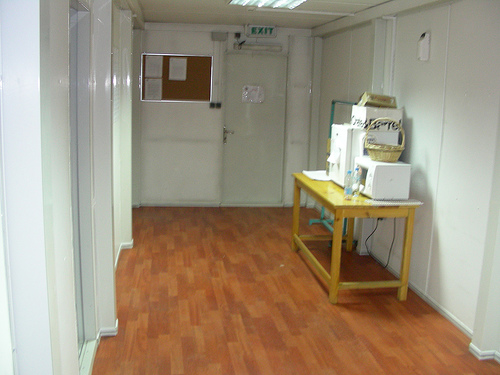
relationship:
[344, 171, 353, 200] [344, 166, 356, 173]
bottles with tops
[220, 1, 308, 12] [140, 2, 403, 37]
light on ceiling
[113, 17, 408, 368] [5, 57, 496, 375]
hallway in building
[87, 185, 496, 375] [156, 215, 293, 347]
floors in hall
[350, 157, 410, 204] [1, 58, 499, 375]
microwave in hall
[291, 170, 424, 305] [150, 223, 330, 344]
table in hall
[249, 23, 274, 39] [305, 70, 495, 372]
sign on wall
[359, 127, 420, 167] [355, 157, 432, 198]
basket over oven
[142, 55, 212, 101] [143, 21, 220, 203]
cork board on wall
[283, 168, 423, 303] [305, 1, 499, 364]
table beside wall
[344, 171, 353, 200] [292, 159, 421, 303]
bottles on table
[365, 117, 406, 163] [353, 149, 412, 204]
basket on microwave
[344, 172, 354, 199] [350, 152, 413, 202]
bottles beside microwave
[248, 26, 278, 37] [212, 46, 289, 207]
exit sign above door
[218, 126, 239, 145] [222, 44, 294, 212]
handle on door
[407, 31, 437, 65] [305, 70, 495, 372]
paper on wall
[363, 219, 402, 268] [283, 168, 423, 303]
cord under table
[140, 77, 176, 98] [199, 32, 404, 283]
paper on door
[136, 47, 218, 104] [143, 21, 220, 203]
cork board on wall